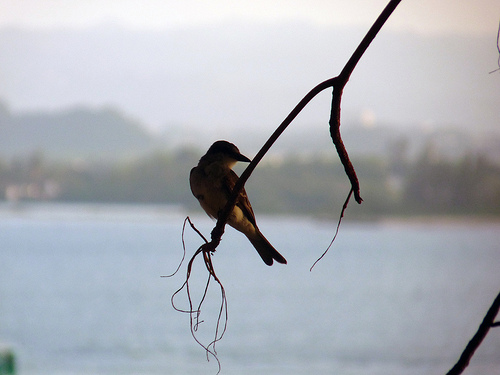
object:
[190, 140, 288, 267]
bird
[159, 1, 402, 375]
branch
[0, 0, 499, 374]
background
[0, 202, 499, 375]
water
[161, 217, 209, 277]
twig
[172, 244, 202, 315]
twig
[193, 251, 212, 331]
twig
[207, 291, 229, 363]
twig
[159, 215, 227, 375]
twig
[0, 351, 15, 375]
object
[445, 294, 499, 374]
branch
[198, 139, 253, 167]
head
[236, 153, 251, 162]
beak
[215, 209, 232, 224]
feet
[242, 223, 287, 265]
tail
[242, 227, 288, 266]
feather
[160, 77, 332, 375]
twig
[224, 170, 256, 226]
wing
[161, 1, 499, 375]
tree